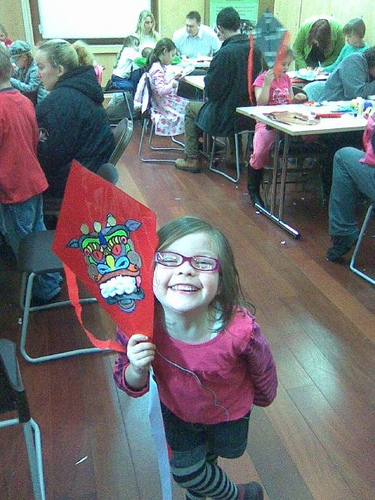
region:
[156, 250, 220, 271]
it is a girl wearing pink glasses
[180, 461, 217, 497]
the girl is wearing white socks with black stripes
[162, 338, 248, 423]
girl is wearing a pink shirt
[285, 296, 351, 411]
the floors are brown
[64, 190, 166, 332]
girl is holding a red kite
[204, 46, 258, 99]
man is wearing a black jacket in the background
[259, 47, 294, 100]
a girl in pink at the table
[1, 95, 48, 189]
boy wearing red shirt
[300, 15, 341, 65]
adult wearing green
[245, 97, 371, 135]
it is a table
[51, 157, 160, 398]
little girl holding a red kite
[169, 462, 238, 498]
blue stripe knee high socks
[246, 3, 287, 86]
little girl holding a blue kite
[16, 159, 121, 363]
a black plastic chair with metal legs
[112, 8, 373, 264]
adults and kids crafting kites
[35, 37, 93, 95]
blonde woman with a pony tail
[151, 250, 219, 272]
girl wearing purple glasses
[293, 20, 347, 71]
person wearing a green jacket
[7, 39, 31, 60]
girl wearing a cap on her head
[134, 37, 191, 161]
a little girl sitting in a chair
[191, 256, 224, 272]
The left portion of a girl's glasses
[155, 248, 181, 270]
The right portion of a girl's glasses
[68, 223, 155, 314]
The design on the girl's kite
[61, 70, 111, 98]
A woman's black hood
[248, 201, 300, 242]
The steel grating of the table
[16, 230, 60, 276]
The front edge of a plastic black seat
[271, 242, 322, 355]
A portion of wooden flooring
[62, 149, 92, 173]
The red tip of the girl's kite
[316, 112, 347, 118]
A red coloring tool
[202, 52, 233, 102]
A poriton of a man's dark coat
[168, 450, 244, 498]
Black and grays striped leggings.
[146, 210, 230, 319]
Purple glasses on young girl.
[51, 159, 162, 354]
Red kite in girl's hand.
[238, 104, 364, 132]
White table by the wall.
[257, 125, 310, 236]
Metal legs on the table.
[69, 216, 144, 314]
Bull character on the kite.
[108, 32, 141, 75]
Hair braid on little girl.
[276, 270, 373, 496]
Hard wood flooring in the room.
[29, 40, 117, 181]
Black jacket on the woman.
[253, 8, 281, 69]
Gray kite in the back of the room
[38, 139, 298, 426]
the girl is proud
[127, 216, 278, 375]
little girl in glasses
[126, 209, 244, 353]
the glasses are pink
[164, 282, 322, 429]
her shirt is pink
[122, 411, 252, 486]
she has striped leggings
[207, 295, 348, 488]
the floor is wooden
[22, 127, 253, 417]
she made the kite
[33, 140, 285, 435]
her kite is red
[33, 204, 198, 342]
the kite has a dragon's face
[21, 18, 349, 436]
many people are making kites